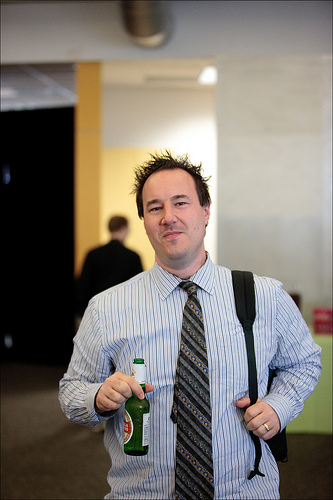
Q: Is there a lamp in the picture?
A: No, there are no lamps.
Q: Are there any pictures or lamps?
A: No, there are no lamps or pictures.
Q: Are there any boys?
A: No, there are no boys.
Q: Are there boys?
A: No, there are no boys.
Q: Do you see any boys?
A: No, there are no boys.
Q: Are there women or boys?
A: No, there are no boys or women.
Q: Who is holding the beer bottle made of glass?
A: The man is holding the beer bottle.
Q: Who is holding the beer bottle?
A: The man is holding the beer bottle.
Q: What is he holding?
A: The man is holding the beer bottle.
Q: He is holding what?
A: The man is holding the beer bottle.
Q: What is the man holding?
A: The man is holding the beer bottle.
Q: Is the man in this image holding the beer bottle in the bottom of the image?
A: Yes, the man is holding the beer bottle.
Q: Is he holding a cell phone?
A: No, the man is holding the beer bottle.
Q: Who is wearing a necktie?
A: The man is wearing a necktie.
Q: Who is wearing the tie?
A: The man is wearing a necktie.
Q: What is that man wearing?
A: The man is wearing a tie.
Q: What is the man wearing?
A: The man is wearing a tie.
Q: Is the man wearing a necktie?
A: Yes, the man is wearing a necktie.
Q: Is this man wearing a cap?
A: No, the man is wearing a necktie.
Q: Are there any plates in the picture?
A: No, there are no plates.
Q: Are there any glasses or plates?
A: No, there are no plates or glasses.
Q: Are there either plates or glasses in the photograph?
A: No, there are no plates or glasses.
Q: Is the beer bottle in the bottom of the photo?
A: Yes, the beer bottle is in the bottom of the image.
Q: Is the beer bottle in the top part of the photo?
A: No, the beer bottle is in the bottom of the image.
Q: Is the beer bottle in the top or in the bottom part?
A: The beer bottle is in the bottom of the image.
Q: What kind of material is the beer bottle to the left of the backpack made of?
A: The beer bottle is made of glass.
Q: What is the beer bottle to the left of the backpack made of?
A: The beer bottle is made of glass.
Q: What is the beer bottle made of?
A: The beer bottle is made of glass.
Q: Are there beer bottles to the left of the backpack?
A: Yes, there is a beer bottle to the left of the backpack.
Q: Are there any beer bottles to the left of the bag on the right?
A: Yes, there is a beer bottle to the left of the backpack.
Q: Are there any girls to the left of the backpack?
A: No, there is a beer bottle to the left of the backpack.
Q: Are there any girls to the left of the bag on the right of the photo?
A: No, there is a beer bottle to the left of the backpack.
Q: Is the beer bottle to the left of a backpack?
A: Yes, the beer bottle is to the left of a backpack.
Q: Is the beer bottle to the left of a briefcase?
A: No, the beer bottle is to the left of a backpack.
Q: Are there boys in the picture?
A: No, there are no boys.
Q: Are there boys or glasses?
A: No, there are no boys or glasses.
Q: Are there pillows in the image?
A: No, there are no pillows.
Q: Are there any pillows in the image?
A: No, there are no pillows.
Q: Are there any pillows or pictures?
A: No, there are no pillows or pictures.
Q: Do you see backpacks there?
A: Yes, there is a backpack.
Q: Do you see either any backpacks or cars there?
A: Yes, there is a backpack.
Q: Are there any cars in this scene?
A: No, there are no cars.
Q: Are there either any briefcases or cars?
A: No, there are no cars or briefcases.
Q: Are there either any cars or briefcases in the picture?
A: No, there are no cars or briefcases.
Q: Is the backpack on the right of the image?
A: Yes, the backpack is on the right of the image.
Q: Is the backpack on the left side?
A: No, the backpack is on the right of the image.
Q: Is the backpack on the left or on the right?
A: The backpack is on the right of the image.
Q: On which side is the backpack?
A: The backpack is on the right of the image.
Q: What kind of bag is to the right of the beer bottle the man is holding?
A: The bag is a backpack.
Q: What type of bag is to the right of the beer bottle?
A: The bag is a backpack.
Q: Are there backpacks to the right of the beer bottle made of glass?
A: Yes, there is a backpack to the right of the beer bottle.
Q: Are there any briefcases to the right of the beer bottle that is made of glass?
A: No, there is a backpack to the right of the beer bottle.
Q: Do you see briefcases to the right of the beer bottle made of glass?
A: No, there is a backpack to the right of the beer bottle.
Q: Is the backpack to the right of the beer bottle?
A: Yes, the backpack is to the right of the beer bottle.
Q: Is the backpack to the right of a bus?
A: No, the backpack is to the right of the beer bottle.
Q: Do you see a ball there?
A: No, there are no balls.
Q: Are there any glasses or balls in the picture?
A: No, there are no balls or glasses.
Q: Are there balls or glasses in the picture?
A: No, there are no balls or glasses.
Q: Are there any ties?
A: Yes, there is a tie.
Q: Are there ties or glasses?
A: Yes, there is a tie.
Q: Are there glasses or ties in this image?
A: Yes, there is a tie.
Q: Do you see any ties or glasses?
A: Yes, there is a tie.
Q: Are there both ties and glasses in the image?
A: No, there is a tie but no glasses.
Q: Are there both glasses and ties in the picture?
A: No, there is a tie but no glasses.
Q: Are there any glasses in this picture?
A: No, there are no glasses.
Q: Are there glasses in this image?
A: No, there are no glasses.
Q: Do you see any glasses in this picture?
A: No, there are no glasses.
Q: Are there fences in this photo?
A: No, there are no fences.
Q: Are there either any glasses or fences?
A: No, there are no fences or glasses.